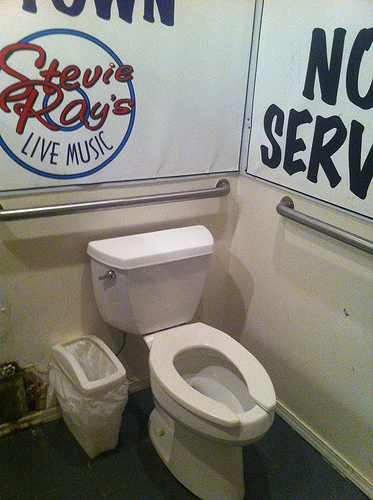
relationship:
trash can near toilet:
[50, 331, 126, 463] [86, 223, 292, 499]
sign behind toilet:
[0, 1, 240, 177] [86, 223, 292, 499]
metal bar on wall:
[0, 176, 232, 224] [1, 2, 257, 427]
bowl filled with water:
[144, 332, 276, 476] [191, 367, 228, 386]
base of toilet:
[151, 405, 251, 500] [86, 223, 292, 499]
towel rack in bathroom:
[0, 176, 232, 224] [1, 2, 365, 490]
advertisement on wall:
[0, 1, 240, 177] [1, 2, 257, 427]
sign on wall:
[0, 1, 240, 177] [1, 2, 257, 427]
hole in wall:
[26, 362, 45, 415] [1, 2, 257, 427]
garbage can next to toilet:
[50, 331, 126, 463] [86, 223, 292, 499]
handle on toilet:
[96, 269, 117, 284] [86, 223, 292, 499]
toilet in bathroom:
[86, 223, 292, 499] [1, 2, 365, 490]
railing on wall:
[0, 176, 232, 224] [1, 2, 257, 427]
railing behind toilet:
[0, 176, 232, 224] [86, 223, 292, 499]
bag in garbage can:
[45, 338, 129, 430] [50, 331, 126, 463]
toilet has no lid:
[86, 223, 292, 499] [151, 321, 278, 429]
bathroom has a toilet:
[1, 2, 365, 490] [86, 223, 292, 499]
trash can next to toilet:
[50, 331, 126, 463] [86, 223, 292, 499]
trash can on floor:
[50, 331, 126, 463] [5, 425, 143, 500]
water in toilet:
[191, 367, 228, 386] [86, 223, 292, 499]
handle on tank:
[96, 271, 113, 287] [87, 220, 218, 332]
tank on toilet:
[87, 220, 218, 332] [86, 223, 292, 499]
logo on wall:
[0, 25, 139, 178] [1, 2, 257, 427]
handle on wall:
[0, 176, 232, 224] [1, 2, 257, 427]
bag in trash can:
[74, 347, 99, 369] [50, 331, 126, 463]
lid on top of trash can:
[48, 333, 130, 391] [50, 331, 126, 463]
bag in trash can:
[45, 338, 129, 430] [50, 331, 126, 463]